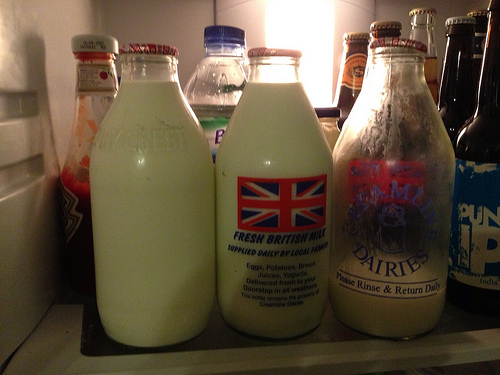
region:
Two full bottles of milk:
[73, 40, 332, 360]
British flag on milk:
[228, 161, 325, 281]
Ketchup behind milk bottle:
[61, 32, 130, 319]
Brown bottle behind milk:
[337, 32, 367, 143]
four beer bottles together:
[406, 7, 499, 295]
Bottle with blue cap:
[176, 22, 262, 159]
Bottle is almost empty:
[341, 38, 473, 337]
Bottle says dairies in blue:
[321, 142, 449, 324]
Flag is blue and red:
[224, 161, 338, 266]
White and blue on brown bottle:
[455, 16, 496, 266]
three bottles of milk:
[89, 21, 486, 357]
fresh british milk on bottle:
[219, 137, 361, 272]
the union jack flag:
[213, 161, 360, 288]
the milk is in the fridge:
[70, 0, 497, 280]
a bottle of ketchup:
[39, 15, 191, 326]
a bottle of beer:
[421, 8, 498, 167]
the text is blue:
[221, 161, 343, 348]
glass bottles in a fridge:
[21, 12, 489, 311]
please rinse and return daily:
[324, 255, 462, 336]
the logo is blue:
[334, 150, 457, 301]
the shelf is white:
[225, 342, 392, 370]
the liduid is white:
[112, 183, 205, 346]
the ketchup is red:
[59, 168, 98, 278]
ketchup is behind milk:
[64, 105, 220, 334]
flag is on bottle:
[225, 152, 330, 227]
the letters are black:
[230, 233, 330, 310]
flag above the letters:
[237, 165, 328, 310]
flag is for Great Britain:
[232, 162, 327, 235]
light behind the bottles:
[197, 8, 387, 130]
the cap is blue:
[197, 16, 249, 53]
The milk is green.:
[118, 176, 195, 300]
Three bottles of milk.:
[108, 35, 459, 346]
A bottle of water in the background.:
[166, 16, 266, 171]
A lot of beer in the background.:
[331, 3, 499, 336]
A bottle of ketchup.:
[48, 25, 146, 317]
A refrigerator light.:
[254, 0, 350, 111]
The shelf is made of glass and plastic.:
[436, 291, 499, 366]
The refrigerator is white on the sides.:
[2, 49, 47, 258]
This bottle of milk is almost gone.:
[321, 30, 456, 346]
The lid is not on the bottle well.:
[349, 24, 444, 70]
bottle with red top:
[84, 31, 224, 313]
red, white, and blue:
[226, 164, 330, 249]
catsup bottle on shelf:
[47, 24, 100, 344]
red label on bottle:
[326, 134, 468, 229]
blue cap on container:
[192, 21, 250, 123]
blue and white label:
[442, 156, 493, 326]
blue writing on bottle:
[217, 213, 347, 371]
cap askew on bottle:
[367, 29, 454, 101]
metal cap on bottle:
[433, 11, 493, 76]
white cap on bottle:
[59, 21, 143, 91]